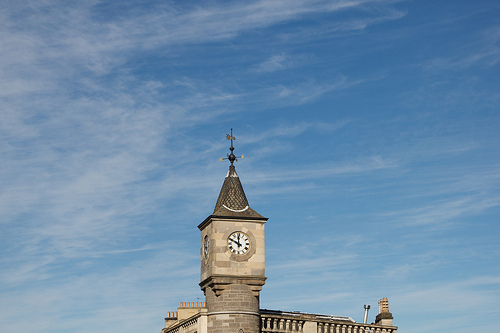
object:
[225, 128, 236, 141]
cross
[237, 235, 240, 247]
black hand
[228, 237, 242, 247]
black hand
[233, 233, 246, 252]
clock face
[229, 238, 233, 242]
numerals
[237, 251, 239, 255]
numerals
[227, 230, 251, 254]
clock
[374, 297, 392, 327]
object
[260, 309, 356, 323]
roof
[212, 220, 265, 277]
bricks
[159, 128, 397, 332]
building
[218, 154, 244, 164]
cross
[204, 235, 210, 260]
clock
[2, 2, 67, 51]
clouds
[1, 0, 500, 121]
sky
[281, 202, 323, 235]
blue water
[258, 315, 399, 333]
balcony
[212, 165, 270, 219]
pointed roof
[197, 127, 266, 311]
clock tower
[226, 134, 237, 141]
vane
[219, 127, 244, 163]
weather vane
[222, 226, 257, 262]
round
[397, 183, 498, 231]
cloud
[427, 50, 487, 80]
cloud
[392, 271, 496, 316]
cloud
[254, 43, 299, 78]
cloud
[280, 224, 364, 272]
cloud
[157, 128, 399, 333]
church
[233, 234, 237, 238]
numeral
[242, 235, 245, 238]
numeral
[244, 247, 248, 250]
numeral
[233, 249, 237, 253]
numeral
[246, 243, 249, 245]
numeral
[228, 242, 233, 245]
numerals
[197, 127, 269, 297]
steeple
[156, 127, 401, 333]
castle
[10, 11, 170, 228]
clouds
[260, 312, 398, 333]
rail